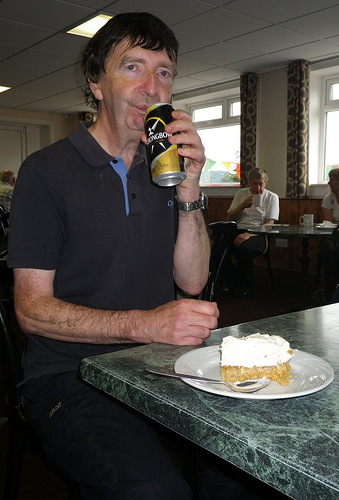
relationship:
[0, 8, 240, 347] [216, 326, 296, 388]
an old man eats cake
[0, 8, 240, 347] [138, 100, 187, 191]
an old man eats beer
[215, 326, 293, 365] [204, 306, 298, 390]
frosting on piece of cake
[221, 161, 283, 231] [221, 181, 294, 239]
man wears white shirt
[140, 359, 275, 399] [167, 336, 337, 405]
spoon on plate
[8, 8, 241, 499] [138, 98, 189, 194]
an old man holds can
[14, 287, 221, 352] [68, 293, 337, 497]
man's right hand on table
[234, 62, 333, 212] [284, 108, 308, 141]
beige curtains has pattern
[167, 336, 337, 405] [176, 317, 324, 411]
plate on pie on round plate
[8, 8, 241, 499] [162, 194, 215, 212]
an old man wears silver watch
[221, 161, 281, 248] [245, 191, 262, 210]
man drinks white coffee cup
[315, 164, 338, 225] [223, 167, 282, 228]
woman talks man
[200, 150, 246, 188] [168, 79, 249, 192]
string of flags out window